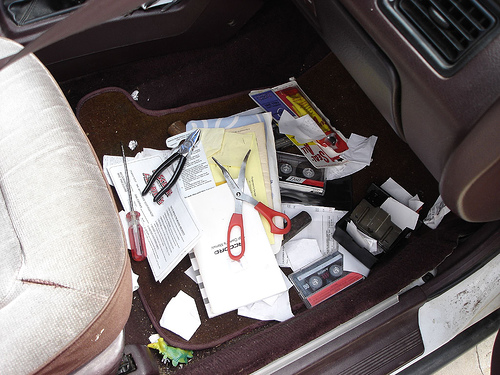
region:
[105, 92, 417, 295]
items on the floorboard of a car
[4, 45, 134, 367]
the seat in the car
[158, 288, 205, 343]
a piece of paper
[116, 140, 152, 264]
a screw driver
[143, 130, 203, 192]
black pliers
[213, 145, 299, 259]
red scissors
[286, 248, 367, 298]
a cassette tape on the floor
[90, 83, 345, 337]
the brown floor mat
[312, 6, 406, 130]
the jockey box in the car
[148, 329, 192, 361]
a green dinosaur figurine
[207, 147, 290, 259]
red pair of scissors.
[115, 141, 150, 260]
Red screwdriver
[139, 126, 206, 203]
Black pliers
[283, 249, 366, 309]
Black and red cassette tape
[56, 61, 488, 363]
Trash covering floorboard of car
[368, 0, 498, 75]
part of a black AC vent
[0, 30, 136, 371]
Cloth seat in car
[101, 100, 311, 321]
sheets of paper covered by tools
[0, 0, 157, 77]
part of a red seatbelt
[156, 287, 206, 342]
folded up receipt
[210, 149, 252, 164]
the scissors are bent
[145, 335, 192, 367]
a green and yellow object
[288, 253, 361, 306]
an old cassette tape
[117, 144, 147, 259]
screwdriver on the floor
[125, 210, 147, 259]
the handle is red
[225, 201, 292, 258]
scissor handles are red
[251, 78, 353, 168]
paper on the ground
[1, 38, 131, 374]
part of a car seat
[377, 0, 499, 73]
an air conditioner vent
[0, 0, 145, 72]
the seat belt is brown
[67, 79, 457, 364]
a lot of papers and other things are on the floor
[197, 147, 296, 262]
a pair of scissors with red handles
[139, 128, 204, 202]
needle nose pliers with black handles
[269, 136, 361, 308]
two cassette tapes lying on the floor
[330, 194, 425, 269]
the car ashtry is on the floor filled with paper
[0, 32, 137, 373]
the passenger seat is tan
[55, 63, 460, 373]
brown carpet is on the floor covered in junk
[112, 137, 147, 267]
a flathead screwdriver with a red handle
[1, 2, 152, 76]
this is part of the brown seatbelt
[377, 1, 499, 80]
the vent is black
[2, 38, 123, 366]
the seat of a car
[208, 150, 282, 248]
scissors on the floor of the car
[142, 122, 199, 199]
pliers on the floor of the car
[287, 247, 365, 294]
a black cassette tape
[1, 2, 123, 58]
the seat belt in the car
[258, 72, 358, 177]
papers on the floor of the car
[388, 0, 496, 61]
an air vent in the car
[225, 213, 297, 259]
the red handle of the scissors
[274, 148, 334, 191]
a tape on the floor